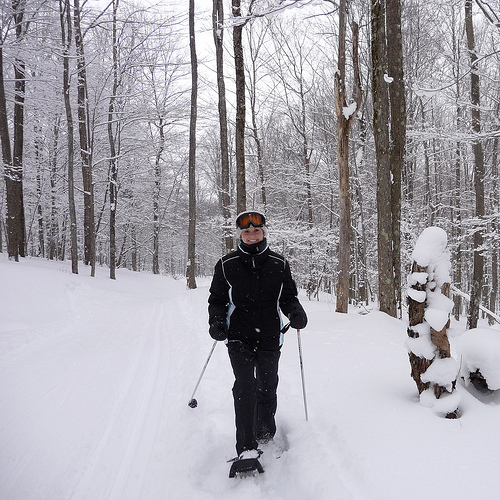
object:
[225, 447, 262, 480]
shoe